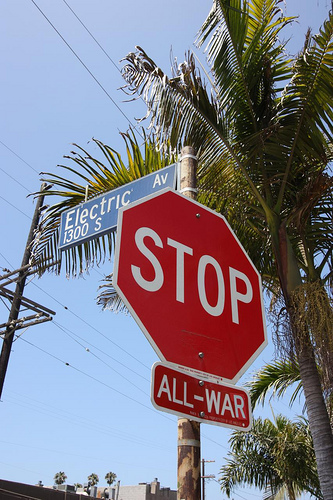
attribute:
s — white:
[128, 223, 172, 297]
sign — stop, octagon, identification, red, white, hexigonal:
[110, 194, 258, 373]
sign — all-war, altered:
[161, 363, 253, 419]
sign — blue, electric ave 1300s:
[47, 175, 193, 236]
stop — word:
[120, 224, 257, 333]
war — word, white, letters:
[208, 392, 246, 422]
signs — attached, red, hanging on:
[78, 148, 252, 421]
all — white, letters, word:
[147, 372, 192, 407]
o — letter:
[192, 243, 227, 320]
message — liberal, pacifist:
[141, 372, 251, 424]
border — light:
[109, 207, 126, 285]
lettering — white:
[120, 231, 258, 317]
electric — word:
[48, 188, 131, 217]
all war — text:
[157, 372, 254, 418]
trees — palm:
[211, 17, 329, 493]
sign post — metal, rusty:
[172, 154, 224, 494]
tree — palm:
[204, 2, 331, 500]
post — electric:
[4, 175, 44, 355]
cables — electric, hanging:
[32, 310, 146, 414]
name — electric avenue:
[62, 181, 134, 220]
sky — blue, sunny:
[8, 8, 159, 152]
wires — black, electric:
[44, 5, 157, 129]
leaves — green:
[217, 8, 326, 222]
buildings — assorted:
[0, 462, 197, 499]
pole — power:
[2, 172, 51, 392]